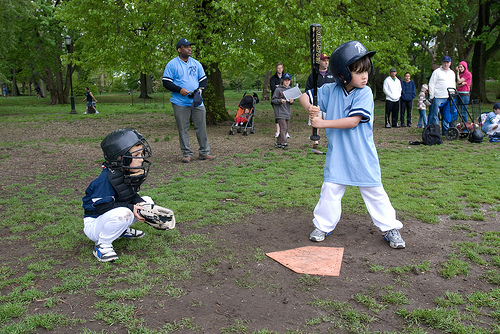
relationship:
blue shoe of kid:
[96, 239, 114, 268] [73, 141, 199, 250]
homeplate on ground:
[272, 227, 353, 281] [242, 266, 274, 304]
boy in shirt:
[313, 35, 410, 249] [311, 82, 385, 171]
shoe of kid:
[121, 221, 150, 244] [73, 141, 199, 250]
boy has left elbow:
[313, 35, 410, 249] [341, 109, 361, 138]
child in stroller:
[236, 106, 252, 127] [229, 88, 268, 141]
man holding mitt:
[156, 35, 219, 156] [190, 86, 207, 106]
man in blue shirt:
[156, 35, 219, 156] [158, 57, 214, 101]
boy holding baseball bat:
[313, 35, 410, 249] [302, 19, 330, 148]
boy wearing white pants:
[313, 35, 410, 249] [309, 179, 416, 228]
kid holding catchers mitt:
[73, 141, 199, 250] [134, 197, 206, 238]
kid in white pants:
[73, 141, 199, 250] [81, 214, 154, 240]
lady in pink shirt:
[453, 54, 473, 128] [456, 74, 475, 100]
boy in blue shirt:
[313, 35, 410, 249] [311, 82, 385, 171]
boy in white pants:
[313, 35, 410, 249] [309, 179, 416, 228]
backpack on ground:
[428, 120, 438, 147] [242, 266, 274, 304]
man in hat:
[156, 35, 219, 156] [160, 37, 213, 53]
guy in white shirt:
[430, 56, 465, 122] [431, 68, 459, 103]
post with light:
[62, 56, 77, 113] [58, 32, 86, 52]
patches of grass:
[160, 159, 193, 186] [187, 181, 299, 202]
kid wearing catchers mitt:
[73, 141, 199, 250] [134, 197, 206, 238]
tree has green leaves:
[169, 11, 246, 39] [100, 11, 132, 62]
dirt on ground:
[226, 235, 289, 251] [242, 266, 274, 304]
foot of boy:
[380, 232, 409, 251] [313, 35, 410, 249]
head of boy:
[346, 61, 377, 80] [313, 35, 410, 249]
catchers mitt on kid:
[134, 197, 206, 238] [73, 141, 199, 250]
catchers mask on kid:
[98, 127, 157, 177] [73, 141, 199, 250]